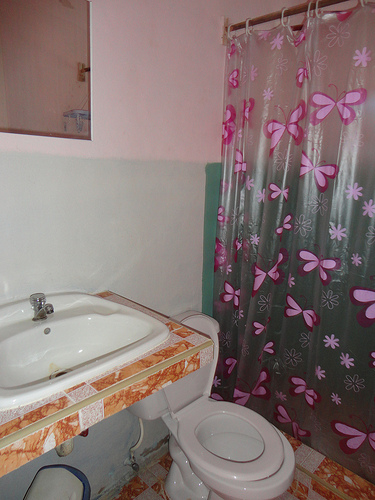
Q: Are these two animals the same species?
A: No, they are bugs and cats.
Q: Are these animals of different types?
A: Yes, they are bugs and cats.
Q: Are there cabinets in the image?
A: No, there are no cabinets.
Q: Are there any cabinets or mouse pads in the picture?
A: No, there are no cabinets or mouse pads.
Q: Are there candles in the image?
A: No, there are no candles.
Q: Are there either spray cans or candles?
A: No, there are no candles or spray cans.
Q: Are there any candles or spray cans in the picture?
A: No, there are no candles or spray cans.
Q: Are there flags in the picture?
A: No, there are no flags.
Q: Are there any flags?
A: No, there are no flags.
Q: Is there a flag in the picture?
A: No, there are no flags.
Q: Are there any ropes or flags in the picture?
A: No, there are no flags or ropes.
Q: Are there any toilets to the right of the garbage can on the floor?
A: Yes, there is a toilet to the right of the garbage bin.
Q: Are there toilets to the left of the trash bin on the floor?
A: No, the toilet is to the right of the trashcan.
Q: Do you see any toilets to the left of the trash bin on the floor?
A: No, the toilet is to the right of the trashcan.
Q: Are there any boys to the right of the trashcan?
A: No, there is a toilet to the right of the trashcan.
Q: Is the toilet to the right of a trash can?
A: Yes, the toilet is to the right of a trash can.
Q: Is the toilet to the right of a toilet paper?
A: No, the toilet is to the right of a trash can.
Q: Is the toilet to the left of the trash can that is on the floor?
A: No, the toilet is to the right of the garbage bin.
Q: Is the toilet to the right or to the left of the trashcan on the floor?
A: The toilet is to the right of the garbage bin.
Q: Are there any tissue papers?
A: No, there are no tissue papers.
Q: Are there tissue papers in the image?
A: No, there are no tissue papers.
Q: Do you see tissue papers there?
A: No, there are no tissue papers.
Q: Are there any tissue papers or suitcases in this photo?
A: No, there are no tissue papers or suitcases.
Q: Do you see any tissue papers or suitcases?
A: No, there are no tissue papers or suitcases.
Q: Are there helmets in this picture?
A: No, there are no helmets.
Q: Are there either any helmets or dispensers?
A: No, there are no helmets or dispensers.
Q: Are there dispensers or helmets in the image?
A: No, there are no helmets or dispensers.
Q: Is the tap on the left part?
A: Yes, the tap is on the left of the image.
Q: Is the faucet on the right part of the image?
A: No, the faucet is on the left of the image.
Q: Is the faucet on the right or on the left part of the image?
A: The faucet is on the left of the image.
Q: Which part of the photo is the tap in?
A: The tap is on the left of the image.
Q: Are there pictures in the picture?
A: No, there are no pictures.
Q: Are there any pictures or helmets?
A: No, there are no pictures or helmets.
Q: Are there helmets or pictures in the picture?
A: No, there are no pictures or helmets.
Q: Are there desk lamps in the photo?
A: No, there are no desk lamps.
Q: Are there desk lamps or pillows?
A: No, there are no desk lamps or pillows.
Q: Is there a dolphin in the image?
A: No, there are no dolphins.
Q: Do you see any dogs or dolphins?
A: No, there are no dolphins or dogs.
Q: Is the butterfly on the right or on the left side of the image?
A: The butterfly is on the right of the image.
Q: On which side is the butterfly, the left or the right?
A: The butterfly is on the right of the image.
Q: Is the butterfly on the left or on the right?
A: The butterfly is on the right of the image.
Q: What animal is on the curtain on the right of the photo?
A: The butterfly is on the curtain.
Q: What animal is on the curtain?
A: The butterfly is on the curtain.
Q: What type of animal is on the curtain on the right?
A: The animal is a butterfly.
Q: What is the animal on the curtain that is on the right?
A: The animal is a butterfly.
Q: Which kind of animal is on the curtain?
A: The animal is a butterfly.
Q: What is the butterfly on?
A: The butterfly is on the curtain.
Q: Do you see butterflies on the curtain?
A: Yes, there is a butterfly on the curtain.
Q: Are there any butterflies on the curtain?
A: Yes, there is a butterfly on the curtain.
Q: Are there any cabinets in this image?
A: No, there are no cabinets.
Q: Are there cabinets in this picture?
A: No, there are no cabinets.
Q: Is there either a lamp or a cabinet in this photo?
A: No, there are no cabinets or lamps.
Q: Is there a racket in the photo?
A: No, there are no rackets.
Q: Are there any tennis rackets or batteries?
A: No, there are no tennis rackets or batteries.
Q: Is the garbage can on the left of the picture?
A: Yes, the garbage can is on the left of the image.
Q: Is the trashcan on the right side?
A: No, the trashcan is on the left of the image.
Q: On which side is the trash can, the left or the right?
A: The trash can is on the left of the image.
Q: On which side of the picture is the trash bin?
A: The trash bin is on the left of the image.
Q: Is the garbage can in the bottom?
A: Yes, the garbage can is in the bottom of the image.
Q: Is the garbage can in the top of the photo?
A: No, the garbage can is in the bottom of the image.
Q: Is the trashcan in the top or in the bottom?
A: The trashcan is in the bottom of the image.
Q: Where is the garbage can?
A: The garbage can is on the floor.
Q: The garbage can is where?
A: The garbage can is on the floor.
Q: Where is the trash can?
A: The garbage can is on the floor.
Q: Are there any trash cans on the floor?
A: Yes, there is a trash can on the floor.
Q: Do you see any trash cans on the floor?
A: Yes, there is a trash can on the floor.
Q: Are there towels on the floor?
A: No, there is a trash can on the floor.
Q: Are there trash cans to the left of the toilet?
A: Yes, there is a trash can to the left of the toilet.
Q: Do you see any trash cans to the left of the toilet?
A: Yes, there is a trash can to the left of the toilet.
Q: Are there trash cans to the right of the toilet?
A: No, the trash can is to the left of the toilet.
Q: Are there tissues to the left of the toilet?
A: No, there is a trash can to the left of the toilet.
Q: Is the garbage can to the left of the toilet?
A: Yes, the garbage can is to the left of the toilet.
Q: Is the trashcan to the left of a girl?
A: No, the trashcan is to the left of the toilet.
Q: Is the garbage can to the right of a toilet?
A: No, the garbage can is to the left of a toilet.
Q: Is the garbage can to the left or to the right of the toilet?
A: The garbage can is to the left of the toilet.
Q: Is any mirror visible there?
A: Yes, there is a mirror.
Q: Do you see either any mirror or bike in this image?
A: Yes, there is a mirror.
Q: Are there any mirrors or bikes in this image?
A: Yes, there is a mirror.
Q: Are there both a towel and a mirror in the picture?
A: No, there is a mirror but no towels.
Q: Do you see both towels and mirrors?
A: No, there is a mirror but no towels.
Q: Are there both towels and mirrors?
A: No, there is a mirror but no towels.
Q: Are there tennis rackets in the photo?
A: No, there are no tennis rackets.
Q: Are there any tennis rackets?
A: No, there are no tennis rackets.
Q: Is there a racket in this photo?
A: No, there are no rackets.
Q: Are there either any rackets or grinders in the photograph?
A: No, there are no rackets or grinders.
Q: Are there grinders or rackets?
A: No, there are no rackets or grinders.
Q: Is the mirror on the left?
A: Yes, the mirror is on the left of the image.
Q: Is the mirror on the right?
A: No, the mirror is on the left of the image.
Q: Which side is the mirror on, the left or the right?
A: The mirror is on the left of the image.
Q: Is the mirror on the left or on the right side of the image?
A: The mirror is on the left of the image.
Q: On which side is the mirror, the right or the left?
A: The mirror is on the left of the image.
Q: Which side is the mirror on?
A: The mirror is on the left of the image.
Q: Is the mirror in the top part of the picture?
A: Yes, the mirror is in the top of the image.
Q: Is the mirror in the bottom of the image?
A: No, the mirror is in the top of the image.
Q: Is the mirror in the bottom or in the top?
A: The mirror is in the top of the image.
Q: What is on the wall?
A: The mirror is on the wall.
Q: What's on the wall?
A: The mirror is on the wall.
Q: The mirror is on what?
A: The mirror is on the wall.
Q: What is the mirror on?
A: The mirror is on the wall.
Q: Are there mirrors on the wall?
A: Yes, there is a mirror on the wall.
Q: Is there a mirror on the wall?
A: Yes, there is a mirror on the wall.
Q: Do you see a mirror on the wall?
A: Yes, there is a mirror on the wall.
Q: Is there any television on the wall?
A: No, there is a mirror on the wall.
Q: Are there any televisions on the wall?
A: No, there is a mirror on the wall.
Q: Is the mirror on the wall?
A: Yes, the mirror is on the wall.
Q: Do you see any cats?
A: Yes, there is a cat.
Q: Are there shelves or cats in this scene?
A: Yes, there is a cat.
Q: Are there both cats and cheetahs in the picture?
A: No, there is a cat but no cheetahs.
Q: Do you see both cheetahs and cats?
A: No, there is a cat but no cheetahs.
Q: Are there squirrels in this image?
A: No, there are no squirrels.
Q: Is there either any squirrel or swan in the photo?
A: No, there are no squirrels or swans.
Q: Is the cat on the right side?
A: Yes, the cat is on the right of the image.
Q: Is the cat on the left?
A: No, the cat is on the right of the image.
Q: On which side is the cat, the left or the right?
A: The cat is on the right of the image.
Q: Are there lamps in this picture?
A: No, there are no lamps.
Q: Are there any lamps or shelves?
A: No, there are no lamps or shelves.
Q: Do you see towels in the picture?
A: No, there are no towels.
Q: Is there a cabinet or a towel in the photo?
A: No, there are no towels or cabinets.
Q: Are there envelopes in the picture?
A: No, there are no envelopes.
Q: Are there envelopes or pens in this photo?
A: No, there are no envelopes or pens.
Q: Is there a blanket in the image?
A: No, there are no blankets.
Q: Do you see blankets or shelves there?
A: No, there are no blankets or shelves.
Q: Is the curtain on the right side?
A: Yes, the curtain is on the right of the image.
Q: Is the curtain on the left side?
A: No, the curtain is on the right of the image.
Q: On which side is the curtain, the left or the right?
A: The curtain is on the right of the image.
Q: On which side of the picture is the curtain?
A: The curtain is on the right of the image.